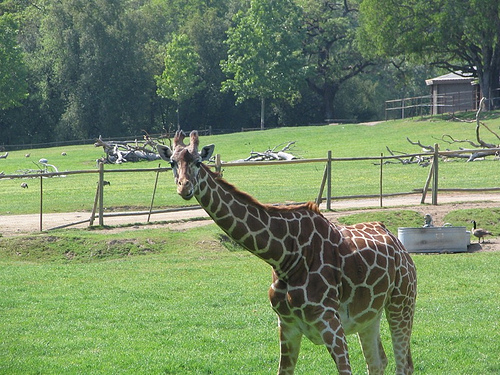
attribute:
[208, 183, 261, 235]
spot — brown 